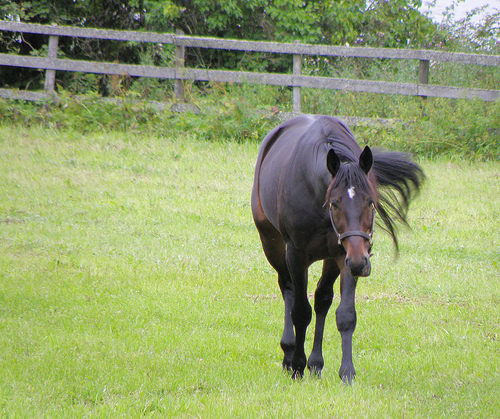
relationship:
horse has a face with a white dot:
[217, 102, 431, 390] [340, 169, 380, 210]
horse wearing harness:
[217, 102, 431, 390] [321, 223, 382, 248]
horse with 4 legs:
[217, 102, 431, 390] [266, 263, 386, 378]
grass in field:
[448, 167, 493, 192] [47, 145, 124, 254]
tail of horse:
[377, 151, 421, 228] [217, 102, 431, 390]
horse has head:
[217, 102, 431, 390] [299, 143, 391, 282]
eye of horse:
[355, 188, 377, 220] [217, 102, 431, 390]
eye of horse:
[317, 196, 349, 225] [217, 102, 431, 390]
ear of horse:
[318, 144, 347, 183] [217, 102, 431, 390]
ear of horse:
[365, 137, 388, 184] [217, 102, 431, 390]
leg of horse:
[284, 245, 319, 375] [217, 102, 431, 390]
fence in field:
[392, 50, 481, 113] [47, 145, 124, 254]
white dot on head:
[340, 169, 380, 210] [299, 143, 391, 282]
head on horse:
[299, 143, 391, 282] [217, 102, 431, 390]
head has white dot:
[299, 143, 391, 282] [340, 169, 380, 210]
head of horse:
[299, 143, 391, 282] [217, 102, 431, 390]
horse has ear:
[217, 102, 431, 390] [318, 144, 347, 183]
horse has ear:
[217, 102, 431, 390] [365, 137, 388, 184]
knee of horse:
[290, 288, 322, 330] [217, 102, 431, 390]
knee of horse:
[276, 279, 289, 292] [217, 102, 431, 390]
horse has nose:
[217, 102, 431, 390] [348, 245, 369, 280]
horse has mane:
[217, 102, 431, 390] [320, 124, 373, 202]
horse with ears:
[217, 102, 431, 390] [322, 142, 382, 178]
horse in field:
[217, 102, 431, 390] [47, 145, 124, 254]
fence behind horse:
[392, 50, 481, 113] [217, 102, 431, 390]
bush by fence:
[431, 99, 496, 171] [392, 50, 481, 113]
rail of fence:
[190, 29, 366, 57] [392, 50, 481, 113]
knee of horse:
[332, 301, 363, 343] [217, 102, 431, 390]